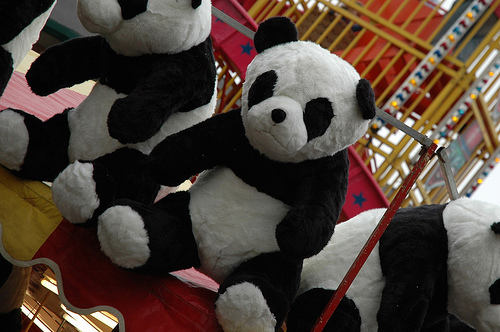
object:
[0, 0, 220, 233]
panda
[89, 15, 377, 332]
panda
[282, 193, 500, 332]
panda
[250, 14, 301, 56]
ear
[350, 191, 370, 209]
star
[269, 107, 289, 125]
nose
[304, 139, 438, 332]
post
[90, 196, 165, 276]
foot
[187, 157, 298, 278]
belly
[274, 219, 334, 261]
paw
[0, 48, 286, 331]
table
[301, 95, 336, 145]
eye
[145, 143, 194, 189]
hand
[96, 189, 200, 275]
leg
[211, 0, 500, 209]
railing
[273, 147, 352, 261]
arm